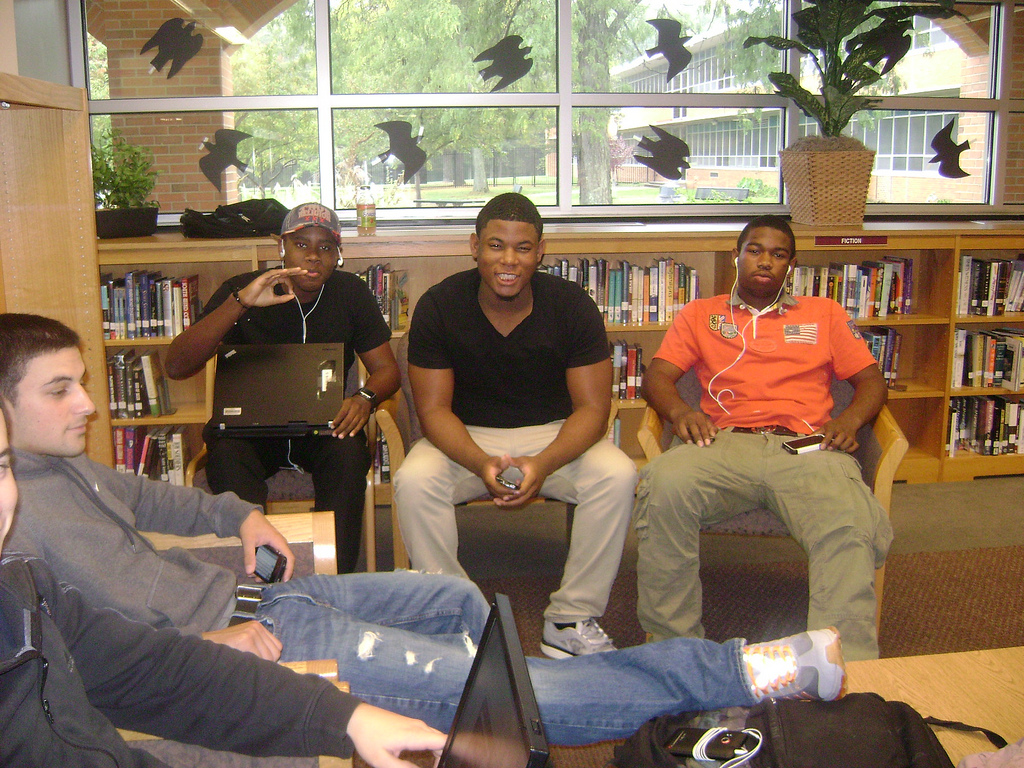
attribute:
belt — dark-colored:
[129, 540, 292, 711]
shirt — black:
[404, 297, 586, 434]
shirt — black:
[188, 262, 409, 446]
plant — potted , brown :
[739, 18, 893, 263]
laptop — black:
[209, 340, 370, 447]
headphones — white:
[710, 253, 793, 420]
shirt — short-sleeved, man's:
[403, 260, 617, 429]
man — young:
[161, 201, 399, 573]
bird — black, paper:
[371, 117, 426, 184]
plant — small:
[743, 3, 968, 137]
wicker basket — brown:
[779, 148, 877, 235]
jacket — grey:
[6, 446, 259, 634]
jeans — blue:
[250, 567, 762, 745]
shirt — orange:
[658, 290, 877, 431]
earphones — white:
[706, 251, 825, 442]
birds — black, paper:
[138, 5, 975, 193]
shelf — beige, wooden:
[94, 217, 1021, 513]